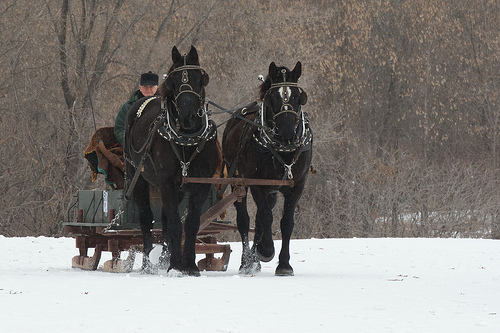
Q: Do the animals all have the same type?
A: Yes, all the animals are horses.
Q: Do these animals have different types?
A: No, all the animals are horses.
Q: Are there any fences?
A: No, there are no fences.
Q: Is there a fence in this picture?
A: No, there are no fences.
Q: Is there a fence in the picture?
A: No, there are no fences.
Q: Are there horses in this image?
A: Yes, there is a horse.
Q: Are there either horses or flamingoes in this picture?
A: Yes, there is a horse.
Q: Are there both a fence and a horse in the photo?
A: No, there is a horse but no fences.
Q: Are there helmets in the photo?
A: No, there are no helmets.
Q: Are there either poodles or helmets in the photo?
A: No, there are no helmets or poodles.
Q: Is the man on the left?
A: Yes, the man is on the left of the image.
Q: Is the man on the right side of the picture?
A: No, the man is on the left of the image.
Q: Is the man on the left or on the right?
A: The man is on the left of the image.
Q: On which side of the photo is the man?
A: The man is on the left of the image.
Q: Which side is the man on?
A: The man is on the left of the image.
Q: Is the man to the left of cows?
A: No, the man is to the left of the horses.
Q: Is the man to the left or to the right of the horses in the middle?
A: The man is to the left of the horses.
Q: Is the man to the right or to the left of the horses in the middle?
A: The man is to the left of the horses.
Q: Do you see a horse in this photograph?
A: Yes, there are horses.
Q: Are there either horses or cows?
A: Yes, there are horses.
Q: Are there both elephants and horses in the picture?
A: No, there are horses but no elephants.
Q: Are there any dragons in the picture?
A: No, there are no dragons.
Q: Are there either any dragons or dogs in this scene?
A: No, there are no dragons or dogs.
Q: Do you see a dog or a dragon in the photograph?
A: No, there are no dragons or dogs.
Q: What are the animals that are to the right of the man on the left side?
A: The animals are horses.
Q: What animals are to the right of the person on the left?
A: The animals are horses.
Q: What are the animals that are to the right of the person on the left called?
A: The animals are horses.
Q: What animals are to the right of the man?
A: The animals are horses.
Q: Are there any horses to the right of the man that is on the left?
A: Yes, there are horses to the right of the man.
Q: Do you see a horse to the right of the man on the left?
A: Yes, there are horses to the right of the man.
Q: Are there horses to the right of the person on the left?
A: Yes, there are horses to the right of the man.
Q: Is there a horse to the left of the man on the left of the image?
A: No, the horses are to the right of the man.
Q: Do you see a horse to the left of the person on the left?
A: No, the horses are to the right of the man.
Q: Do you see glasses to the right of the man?
A: No, there are horses to the right of the man.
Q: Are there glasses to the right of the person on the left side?
A: No, there are horses to the right of the man.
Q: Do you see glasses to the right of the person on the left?
A: No, there are horses to the right of the man.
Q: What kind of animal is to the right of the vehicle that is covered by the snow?
A: The animals are horses.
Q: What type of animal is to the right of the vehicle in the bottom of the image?
A: The animals are horses.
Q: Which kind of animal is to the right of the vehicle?
A: The animals are horses.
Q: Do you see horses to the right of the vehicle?
A: Yes, there are horses to the right of the vehicle.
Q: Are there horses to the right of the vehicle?
A: Yes, there are horses to the right of the vehicle.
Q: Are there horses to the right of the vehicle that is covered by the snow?
A: Yes, there are horses to the right of the vehicle.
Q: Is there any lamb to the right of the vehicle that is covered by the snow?
A: No, there are horses to the right of the vehicle.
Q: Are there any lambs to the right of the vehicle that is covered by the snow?
A: No, there are horses to the right of the vehicle.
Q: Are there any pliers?
A: No, there are no pliers.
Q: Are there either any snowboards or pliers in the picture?
A: No, there are no pliers or snowboards.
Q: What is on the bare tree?
A: The trunks are on the tree.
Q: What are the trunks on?
A: The trunks are on the tree.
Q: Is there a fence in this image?
A: No, there are no fences.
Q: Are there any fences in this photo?
A: No, there are no fences.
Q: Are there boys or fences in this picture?
A: No, there are no fences or boys.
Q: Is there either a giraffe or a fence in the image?
A: No, there are no fences or giraffes.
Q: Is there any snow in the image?
A: Yes, there is snow.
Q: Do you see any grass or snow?
A: Yes, there is snow.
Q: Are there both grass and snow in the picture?
A: No, there is snow but no grass.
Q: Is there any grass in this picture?
A: No, there is no grass.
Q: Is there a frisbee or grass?
A: No, there are no grass or frisbees.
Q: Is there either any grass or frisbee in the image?
A: No, there are no grass or frisbees.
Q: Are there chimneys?
A: No, there are no chimneys.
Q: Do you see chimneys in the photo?
A: No, there are no chimneys.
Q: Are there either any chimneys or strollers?
A: No, there are no chimneys or strollers.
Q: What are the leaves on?
A: The leaves are on the tree.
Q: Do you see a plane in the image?
A: No, there are no airplanes.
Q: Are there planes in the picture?
A: No, there are no planes.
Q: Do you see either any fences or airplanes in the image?
A: No, there are no airplanes or fences.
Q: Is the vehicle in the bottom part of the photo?
A: Yes, the vehicle is in the bottom of the image.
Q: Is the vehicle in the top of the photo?
A: No, the vehicle is in the bottom of the image.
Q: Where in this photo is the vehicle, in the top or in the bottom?
A: The vehicle is in the bottom of the image.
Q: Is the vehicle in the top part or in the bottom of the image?
A: The vehicle is in the bottom of the image.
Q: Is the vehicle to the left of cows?
A: No, the vehicle is to the left of the horses.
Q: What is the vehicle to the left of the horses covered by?
A: The vehicle is covered by the snow.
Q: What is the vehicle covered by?
A: The vehicle is covered by the snow.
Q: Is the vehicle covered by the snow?
A: Yes, the vehicle is covered by the snow.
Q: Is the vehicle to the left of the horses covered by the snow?
A: Yes, the vehicle is covered by the snow.